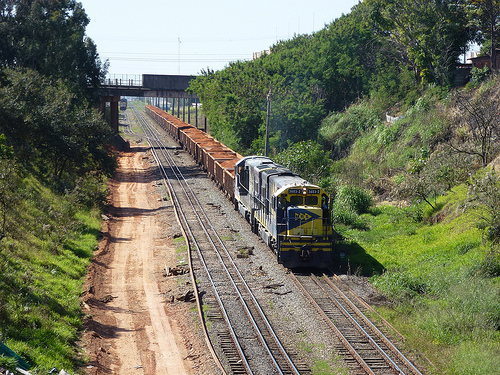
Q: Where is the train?
A: On the tracks.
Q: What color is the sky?
A: Blue.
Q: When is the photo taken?
A: Daytime.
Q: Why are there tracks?
A: For the train.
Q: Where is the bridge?
A: Over the tracks.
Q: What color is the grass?
A: Green.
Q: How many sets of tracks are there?
A: Two.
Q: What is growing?
A: Trees and plants.